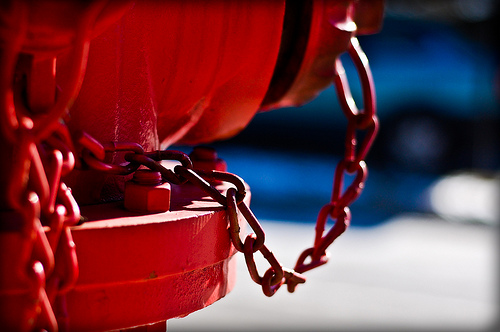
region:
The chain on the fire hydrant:
[111, 69, 394, 289]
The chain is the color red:
[161, 150, 387, 293]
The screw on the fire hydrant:
[122, 167, 172, 184]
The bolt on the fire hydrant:
[121, 180, 179, 213]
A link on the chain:
[325, 156, 368, 211]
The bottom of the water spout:
[237, 1, 342, 128]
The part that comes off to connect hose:
[287, 0, 392, 147]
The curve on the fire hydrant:
[77, 201, 222, 236]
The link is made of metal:
[332, 163, 369, 208]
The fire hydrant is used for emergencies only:
[13, 26, 361, 329]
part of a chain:
[336, 215, 351, 235]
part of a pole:
[173, 275, 190, 284]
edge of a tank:
[154, 231, 164, 243]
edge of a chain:
[289, 253, 297, 264]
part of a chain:
[107, 73, 139, 115]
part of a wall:
[401, 180, 411, 202]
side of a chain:
[256, 278, 267, 292]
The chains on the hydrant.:
[20, 40, 377, 322]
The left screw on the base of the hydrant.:
[127, 160, 173, 207]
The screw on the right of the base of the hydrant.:
[182, 139, 225, 180]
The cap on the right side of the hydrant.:
[293, 1, 382, 112]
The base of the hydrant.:
[5, 200, 248, 330]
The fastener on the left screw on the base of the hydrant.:
[122, 180, 172, 209]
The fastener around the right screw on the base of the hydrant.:
[193, 156, 228, 183]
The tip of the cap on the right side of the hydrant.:
[360, 3, 384, 33]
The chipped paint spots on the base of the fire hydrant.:
[141, 261, 216, 311]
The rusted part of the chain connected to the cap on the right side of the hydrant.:
[219, 172, 322, 302]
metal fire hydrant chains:
[7, 21, 378, 330]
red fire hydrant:
[2, 1, 377, 330]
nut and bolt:
[120, 166, 173, 205]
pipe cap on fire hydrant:
[263, 1, 376, 107]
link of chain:
[334, 159, 368, 200]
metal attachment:
[331, 19, 382, 119]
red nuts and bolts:
[127, 149, 226, 209]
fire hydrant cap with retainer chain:
[1, 1, 381, 298]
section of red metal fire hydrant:
[0, 1, 381, 330]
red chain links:
[9, 120, 80, 330]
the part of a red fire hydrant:
[0, 0, 382, 327]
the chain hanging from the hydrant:
[0, 2, 377, 328]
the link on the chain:
[345, 110, 380, 174]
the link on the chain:
[331, 157, 367, 218]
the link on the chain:
[312, 202, 349, 261]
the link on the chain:
[292, 247, 329, 274]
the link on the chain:
[245, 229, 284, 288]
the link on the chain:
[225, 184, 265, 254]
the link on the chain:
[177, 162, 245, 203]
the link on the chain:
[125, 147, 192, 182]